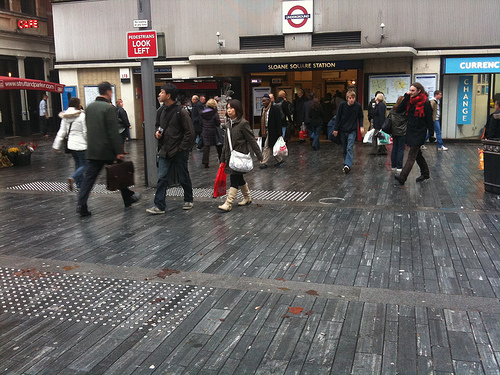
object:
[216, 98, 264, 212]
woman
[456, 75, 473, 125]
sign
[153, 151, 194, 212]
pants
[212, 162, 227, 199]
bag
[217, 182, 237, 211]
boots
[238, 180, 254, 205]
boots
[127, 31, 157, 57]
red sign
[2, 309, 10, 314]
dots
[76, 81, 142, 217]
man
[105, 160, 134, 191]
brief case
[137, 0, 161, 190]
pole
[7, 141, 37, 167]
pot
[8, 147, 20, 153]
flowers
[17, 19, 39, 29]
sign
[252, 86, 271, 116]
sign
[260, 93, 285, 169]
man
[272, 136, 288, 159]
bags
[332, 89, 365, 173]
man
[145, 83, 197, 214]
man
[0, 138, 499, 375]
sidewalk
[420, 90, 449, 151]
man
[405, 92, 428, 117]
scarf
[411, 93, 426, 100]
neck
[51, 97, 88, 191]
lady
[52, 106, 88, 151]
jacket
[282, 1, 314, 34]
sign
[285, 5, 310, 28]
circle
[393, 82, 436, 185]
man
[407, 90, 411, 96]
phone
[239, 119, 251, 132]
shoulder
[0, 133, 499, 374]
ground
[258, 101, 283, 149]
jacket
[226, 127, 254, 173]
pocketbook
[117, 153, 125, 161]
hand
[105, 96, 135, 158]
people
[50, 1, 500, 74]
roof